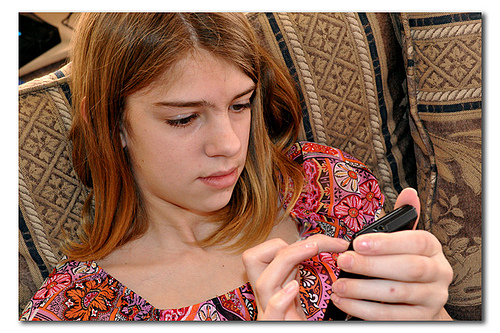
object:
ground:
[403, 119, 427, 136]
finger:
[349, 228, 441, 258]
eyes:
[161, 97, 253, 130]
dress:
[20, 140, 387, 322]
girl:
[17, 12, 456, 322]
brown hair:
[54, 12, 306, 265]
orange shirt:
[17, 140, 389, 324]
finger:
[238, 236, 289, 287]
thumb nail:
[401, 188, 418, 196]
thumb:
[393, 187, 422, 231]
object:
[320, 204, 419, 321]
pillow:
[398, 13, 481, 318]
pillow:
[19, 14, 403, 288]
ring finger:
[330, 278, 430, 306]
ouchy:
[389, 287, 397, 294]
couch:
[18, 12, 480, 322]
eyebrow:
[230, 83, 256, 104]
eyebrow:
[151, 96, 215, 109]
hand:
[327, 187, 457, 321]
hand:
[238, 232, 350, 321]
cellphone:
[321, 202, 419, 321]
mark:
[389, 286, 396, 294]